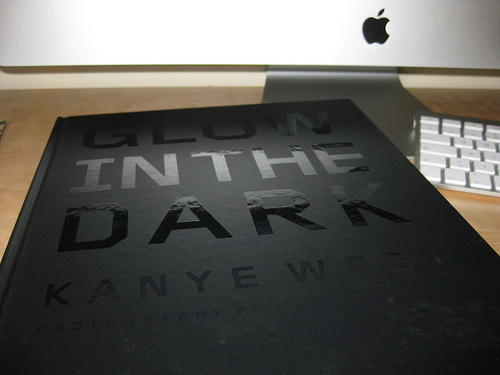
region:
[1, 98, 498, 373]
the book is black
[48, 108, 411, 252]
the text is shining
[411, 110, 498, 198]
a thin apple keyboard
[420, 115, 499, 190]
the keys are white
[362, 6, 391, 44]
a black apple logo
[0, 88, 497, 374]
the desk is beige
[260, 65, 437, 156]
monitor stand is silver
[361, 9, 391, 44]
a picture of an apple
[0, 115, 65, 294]
crease in the book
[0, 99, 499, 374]
the book is flat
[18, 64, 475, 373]
the cover of a CD album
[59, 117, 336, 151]
font written in black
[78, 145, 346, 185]
font that looks very white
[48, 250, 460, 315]
Kanye West's name in black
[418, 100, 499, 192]
the keyboard of a computer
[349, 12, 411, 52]
the logo of a computer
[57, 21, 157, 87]
the boarder of a computer screen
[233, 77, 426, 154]
the base of a computer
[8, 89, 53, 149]
the brown wood of a table top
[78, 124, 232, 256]
light reflecting on an album cover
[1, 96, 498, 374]
A black hard cover book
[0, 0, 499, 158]
A silver Apple monitor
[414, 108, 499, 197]
A silver and white Apple key board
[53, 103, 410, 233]
The title of a book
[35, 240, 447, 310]
The author of a book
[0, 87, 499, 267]
The surface of a wooden desk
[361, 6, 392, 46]
A black Apple logo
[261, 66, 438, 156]
A silver computer monitor stand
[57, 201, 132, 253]
The capital letter D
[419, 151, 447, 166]
A shift key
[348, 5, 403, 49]
black mac logo on mac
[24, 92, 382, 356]
black writing on book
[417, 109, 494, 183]
white keys on keyboard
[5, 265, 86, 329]
black letter on book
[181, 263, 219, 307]
black letter on book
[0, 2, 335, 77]
silver bottom of monitor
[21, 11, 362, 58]
white bottom of monitor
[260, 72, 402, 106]
silver base of monitor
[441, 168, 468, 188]
white key on board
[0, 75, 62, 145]
brown desk below monitor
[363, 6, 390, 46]
small Apple logo on a monitor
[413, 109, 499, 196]
silver keyboard with white keys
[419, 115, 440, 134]
two white keys on a keyboard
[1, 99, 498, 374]
Large black photography book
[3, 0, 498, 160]
silver Apple brand monitor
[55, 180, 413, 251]
The word DARK on a black book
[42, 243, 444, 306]
the name Kanye West on a book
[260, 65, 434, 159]
silver stand on a monitor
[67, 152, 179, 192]
The word IN written on a book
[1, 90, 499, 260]
top of a wooden style desk